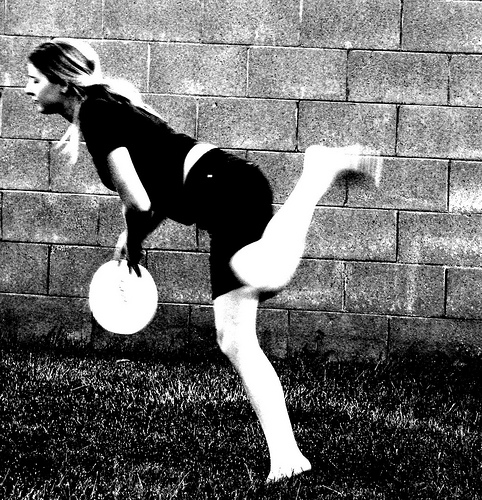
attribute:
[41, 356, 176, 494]
grass — short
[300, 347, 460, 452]
line — white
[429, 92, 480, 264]
chalk — white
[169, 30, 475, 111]
tiles — square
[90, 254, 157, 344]
frisbee — white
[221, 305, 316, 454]
skin — woman's, bare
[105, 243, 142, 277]
fingers — woman's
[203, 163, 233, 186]
spot — small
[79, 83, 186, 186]
shirt — black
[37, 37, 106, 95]
hair — long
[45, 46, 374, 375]
woman — light skinned, bent, leaning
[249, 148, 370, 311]
leg — woman's, bent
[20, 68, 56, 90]
eye — closed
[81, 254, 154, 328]
plate — white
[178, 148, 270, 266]
shorts — black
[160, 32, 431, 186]
wall — brick, cement, block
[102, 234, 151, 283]
hand — girl's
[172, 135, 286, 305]
shorts — black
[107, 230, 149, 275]
hand — woman's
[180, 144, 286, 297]
shorts — black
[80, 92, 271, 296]
clothing — dark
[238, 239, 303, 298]
knee — bent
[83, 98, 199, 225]
shirt — black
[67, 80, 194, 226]
shirt — black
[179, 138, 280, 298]
short — black